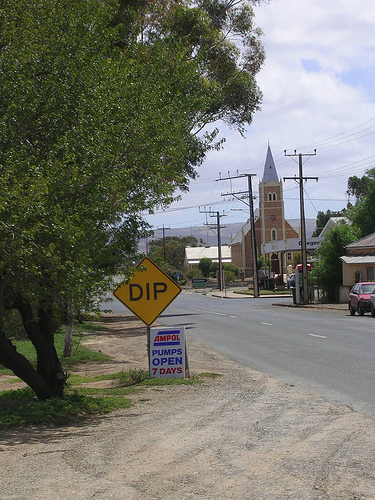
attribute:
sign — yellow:
[111, 259, 186, 323]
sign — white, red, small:
[145, 324, 190, 379]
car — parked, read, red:
[347, 281, 374, 317]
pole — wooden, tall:
[282, 145, 320, 306]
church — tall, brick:
[230, 143, 325, 294]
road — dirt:
[1, 398, 369, 497]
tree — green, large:
[3, 3, 263, 403]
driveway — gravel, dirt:
[3, 382, 368, 499]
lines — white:
[252, 316, 329, 344]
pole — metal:
[137, 320, 157, 377]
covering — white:
[258, 230, 330, 259]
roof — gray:
[182, 246, 237, 268]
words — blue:
[150, 343, 188, 368]